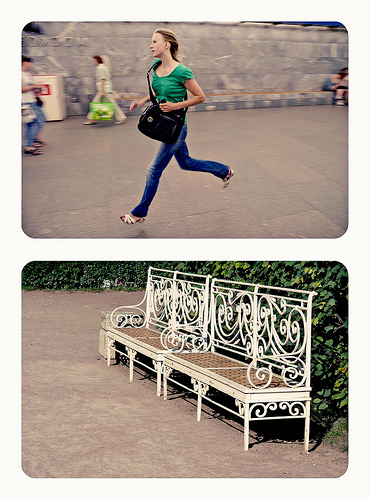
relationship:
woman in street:
[118, 28, 235, 224] [21, 107, 347, 237]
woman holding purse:
[118, 28, 235, 224] [137, 57, 189, 144]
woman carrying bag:
[82, 55, 127, 124] [89, 102, 117, 121]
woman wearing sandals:
[118, 28, 235, 224] [120, 167, 236, 225]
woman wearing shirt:
[118, 28, 235, 224] [150, 63, 196, 115]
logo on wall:
[21, 34, 92, 46] [22, 22, 348, 121]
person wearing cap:
[22, 56, 47, 154] [20, 56, 31, 62]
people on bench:
[320, 65, 349, 108] [73, 91, 347, 117]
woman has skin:
[118, 28, 235, 224] [129, 32, 206, 111]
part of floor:
[42, 314, 76, 383] [27, 294, 96, 477]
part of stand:
[244, 412, 276, 426] [157, 392, 310, 453]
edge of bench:
[248, 386, 309, 405] [161, 278, 318, 448]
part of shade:
[274, 428, 287, 437] [244, 416, 322, 448]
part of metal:
[254, 306, 281, 321] [253, 287, 310, 360]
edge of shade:
[263, 437, 305, 443] [244, 416, 322, 448]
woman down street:
[118, 28, 235, 224] [21, 107, 347, 237]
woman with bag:
[82, 55, 127, 124] [89, 102, 117, 121]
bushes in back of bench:
[290, 262, 350, 416] [161, 278, 318, 448]